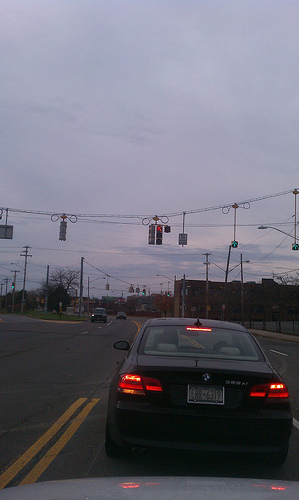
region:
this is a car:
[78, 264, 297, 472]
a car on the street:
[83, 283, 297, 495]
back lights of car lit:
[112, 363, 295, 414]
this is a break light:
[115, 368, 153, 403]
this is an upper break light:
[185, 322, 216, 333]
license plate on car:
[186, 373, 233, 410]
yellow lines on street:
[2, 360, 105, 498]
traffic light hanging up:
[131, 209, 200, 250]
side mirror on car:
[107, 332, 148, 361]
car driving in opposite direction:
[77, 295, 129, 337]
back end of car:
[101, 308, 295, 469]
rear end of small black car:
[96, 308, 295, 472]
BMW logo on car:
[200, 371, 211, 383]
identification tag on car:
[183, 380, 227, 406]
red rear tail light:
[111, 370, 165, 398]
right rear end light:
[245, 379, 289, 405]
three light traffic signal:
[154, 223, 164, 246]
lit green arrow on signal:
[228, 238, 239, 250]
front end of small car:
[114, 309, 127, 321]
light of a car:
[114, 363, 166, 402]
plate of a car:
[187, 373, 228, 412]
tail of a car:
[241, 379, 290, 405]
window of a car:
[142, 323, 265, 363]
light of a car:
[179, 317, 217, 336]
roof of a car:
[159, 317, 235, 334]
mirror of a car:
[110, 339, 141, 353]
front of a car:
[89, 312, 106, 322]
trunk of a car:
[131, 353, 283, 416]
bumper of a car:
[112, 402, 296, 468]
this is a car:
[85, 299, 113, 333]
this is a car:
[111, 305, 128, 329]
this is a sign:
[171, 228, 190, 251]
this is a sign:
[224, 229, 241, 256]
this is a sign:
[287, 235, 296, 256]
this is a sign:
[45, 200, 75, 244]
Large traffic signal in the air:
[282, 188, 297, 260]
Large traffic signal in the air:
[226, 199, 244, 254]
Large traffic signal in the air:
[154, 211, 168, 250]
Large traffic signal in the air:
[140, 210, 154, 249]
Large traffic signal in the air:
[52, 207, 72, 250]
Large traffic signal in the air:
[0, 202, 16, 231]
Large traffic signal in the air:
[141, 285, 148, 296]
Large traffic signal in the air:
[102, 273, 113, 293]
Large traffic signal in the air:
[126, 276, 132, 294]